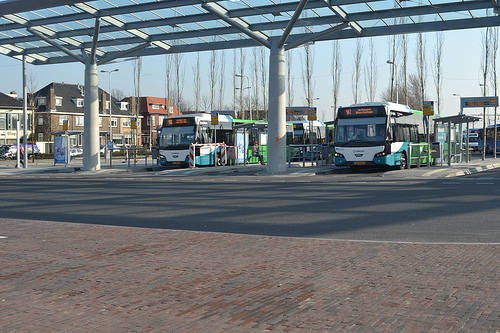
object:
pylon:
[265, 41, 287, 176]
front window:
[161, 125, 196, 151]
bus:
[286, 119, 323, 160]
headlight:
[160, 155, 165, 159]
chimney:
[49, 88, 55, 111]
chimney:
[102, 91, 106, 114]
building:
[0, 82, 188, 156]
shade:
[0, 175, 500, 237]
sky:
[0, 0, 500, 83]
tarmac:
[0, 182, 500, 331]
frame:
[1, 0, 497, 174]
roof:
[1, 0, 497, 66]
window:
[333, 115, 386, 142]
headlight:
[376, 152, 387, 156]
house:
[0, 90, 39, 154]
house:
[27, 82, 142, 157]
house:
[117, 96, 187, 155]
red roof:
[119, 96, 185, 115]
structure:
[0, 0, 500, 185]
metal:
[0, 0, 500, 65]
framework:
[0, 0, 500, 66]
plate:
[173, 161, 180, 164]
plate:
[354, 161, 365, 164]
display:
[335, 107, 387, 118]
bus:
[334, 101, 452, 170]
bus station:
[0, 22, 499, 171]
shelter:
[2, 0, 498, 175]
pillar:
[266, 44, 288, 176]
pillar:
[81, 60, 101, 173]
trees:
[128, 0, 499, 161]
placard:
[53, 131, 70, 167]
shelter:
[49, 129, 113, 158]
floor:
[2, 158, 500, 333]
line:
[0, 216, 499, 246]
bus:
[151, 112, 294, 167]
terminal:
[0, 1, 500, 174]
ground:
[8, 163, 498, 243]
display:
[164, 117, 194, 127]